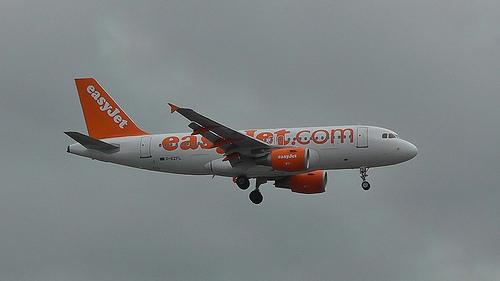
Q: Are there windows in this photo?
A: Yes, there are windows.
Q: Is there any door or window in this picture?
A: Yes, there are windows.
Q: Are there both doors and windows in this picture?
A: Yes, there are both windows and doors.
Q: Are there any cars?
A: No, there are no cars.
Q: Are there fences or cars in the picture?
A: No, there are no cars or fences.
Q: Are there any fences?
A: No, there are no fences.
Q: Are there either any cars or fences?
A: No, there are no fences or cars.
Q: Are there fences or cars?
A: No, there are no fences or cars.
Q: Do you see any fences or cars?
A: No, there are no fences or cars.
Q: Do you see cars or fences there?
A: No, there are no fences or cars.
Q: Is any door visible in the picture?
A: Yes, there is a door.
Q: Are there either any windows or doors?
A: Yes, there is a door.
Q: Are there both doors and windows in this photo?
A: Yes, there are both a door and a window.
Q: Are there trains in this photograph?
A: No, there are no trains.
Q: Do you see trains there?
A: No, there are no trains.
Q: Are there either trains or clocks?
A: No, there are no trains or clocks.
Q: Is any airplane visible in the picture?
A: Yes, there is an airplane.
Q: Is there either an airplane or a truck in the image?
A: Yes, there is an airplane.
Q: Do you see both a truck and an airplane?
A: No, there is an airplane but no trucks.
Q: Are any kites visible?
A: No, there are no kites.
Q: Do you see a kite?
A: No, there are no kites.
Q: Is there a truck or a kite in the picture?
A: No, there are no kites or trucks.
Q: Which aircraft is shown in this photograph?
A: The aircraft is an airplane.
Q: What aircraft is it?
A: The aircraft is an airplane.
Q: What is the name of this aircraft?
A: This is an airplane.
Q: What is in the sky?
A: The plane is in the sky.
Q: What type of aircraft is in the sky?
A: The aircraft is an airplane.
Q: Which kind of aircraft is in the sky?
A: The aircraft is an airplane.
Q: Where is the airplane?
A: The airplane is in the sky.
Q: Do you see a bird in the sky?
A: No, there is an airplane in the sky.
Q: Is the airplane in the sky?
A: Yes, the airplane is in the sky.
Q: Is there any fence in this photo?
A: No, there are no fences.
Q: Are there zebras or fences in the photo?
A: No, there are no fences or zebras.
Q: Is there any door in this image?
A: Yes, there is a door.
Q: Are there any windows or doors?
A: Yes, there is a door.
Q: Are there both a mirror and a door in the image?
A: No, there is a door but no mirrors.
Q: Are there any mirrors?
A: No, there are no mirrors.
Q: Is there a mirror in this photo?
A: No, there are no mirrors.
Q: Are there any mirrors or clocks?
A: No, there are no mirrors or clocks.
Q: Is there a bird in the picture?
A: No, there are no birds.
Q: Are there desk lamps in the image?
A: No, there are no desk lamps.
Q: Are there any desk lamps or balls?
A: No, there are no desk lamps or balls.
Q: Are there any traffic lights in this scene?
A: No, there are no traffic lights.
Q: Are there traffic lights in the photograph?
A: No, there are no traffic lights.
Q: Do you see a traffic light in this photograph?
A: No, there are no traffic lights.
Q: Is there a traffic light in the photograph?
A: No, there are no traffic lights.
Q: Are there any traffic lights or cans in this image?
A: No, there are no traffic lights or cans.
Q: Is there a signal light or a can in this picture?
A: No, there are no traffic lights or cans.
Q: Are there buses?
A: No, there are no buses.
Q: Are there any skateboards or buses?
A: No, there are no buses or skateboards.